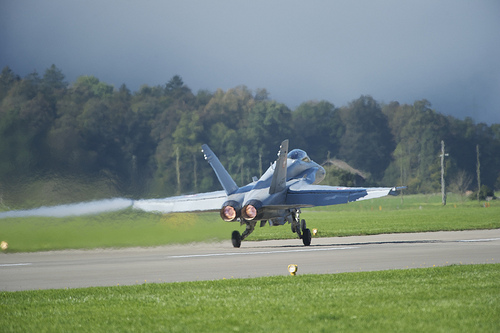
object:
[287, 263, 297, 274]
light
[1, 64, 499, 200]
tree line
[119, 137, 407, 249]
plane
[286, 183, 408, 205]
right wing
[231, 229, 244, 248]
tire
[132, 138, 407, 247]
airplane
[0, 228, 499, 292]
runway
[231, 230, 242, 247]
landing gear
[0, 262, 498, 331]
grass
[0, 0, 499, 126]
clouds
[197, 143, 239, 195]
tail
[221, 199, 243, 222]
engines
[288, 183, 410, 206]
wings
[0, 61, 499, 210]
forest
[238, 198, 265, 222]
turbine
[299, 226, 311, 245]
right tire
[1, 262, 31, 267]
line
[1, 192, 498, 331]
ground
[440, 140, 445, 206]
wooden poles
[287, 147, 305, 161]
cockpit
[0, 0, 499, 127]
sky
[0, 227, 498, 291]
airport runway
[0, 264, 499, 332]
field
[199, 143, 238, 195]
fin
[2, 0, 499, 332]
background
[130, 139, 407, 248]
takeoff